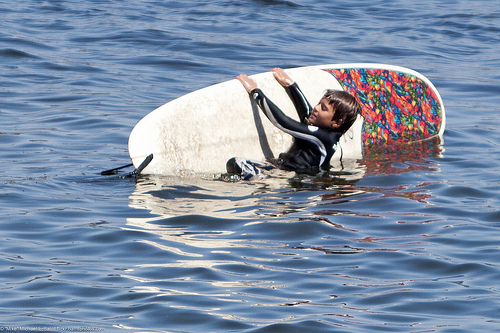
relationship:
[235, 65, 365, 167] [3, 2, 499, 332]
kid in water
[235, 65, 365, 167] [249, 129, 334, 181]
kid wearing wetsuit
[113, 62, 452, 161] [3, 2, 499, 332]
surfboard in water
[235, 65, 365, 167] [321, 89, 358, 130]
kid has hair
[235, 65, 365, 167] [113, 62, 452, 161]
kid holding surfboard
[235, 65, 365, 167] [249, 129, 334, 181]
kid in wetsuit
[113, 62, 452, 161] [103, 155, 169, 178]
surfboard has fins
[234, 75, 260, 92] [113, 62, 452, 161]
left hand on surfboard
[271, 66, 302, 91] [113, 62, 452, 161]
right hand on surfboard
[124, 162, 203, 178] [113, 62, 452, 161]
cord on surfboard